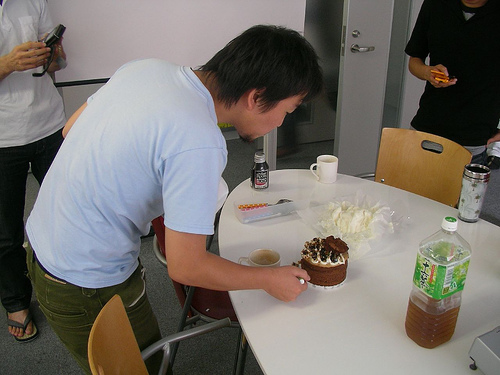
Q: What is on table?
A: A cake.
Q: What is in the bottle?
A: Tea.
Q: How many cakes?
A: One.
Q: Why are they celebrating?
A: Birthday.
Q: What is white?
A: Table.